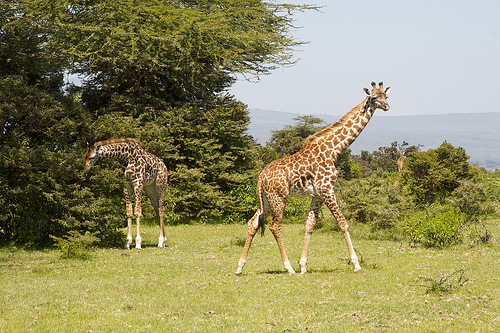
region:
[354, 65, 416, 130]
the head of a giraffe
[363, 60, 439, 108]
the eyes of a giraffe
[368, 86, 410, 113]
the mouth of a giraffe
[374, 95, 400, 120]
the nose of a giraffe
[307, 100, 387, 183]
the neck of a giraffe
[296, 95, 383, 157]
the main of a giraffe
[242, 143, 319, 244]
a tail of a giraffe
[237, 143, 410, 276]
the legs of a giraffe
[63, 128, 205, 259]
a book near a tree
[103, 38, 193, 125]
green leaves on a tree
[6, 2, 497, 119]
clear light blue sky with no clouds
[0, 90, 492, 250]
tall bushes planted behind giraffes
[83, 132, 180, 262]
baby giraffe eating bushes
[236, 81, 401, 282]
young giraffe standing in grassy field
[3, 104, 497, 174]
tall mountains sitting in background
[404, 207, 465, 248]
small bush sitting near giraffe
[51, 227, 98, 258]
smaller bush sitting near larger bush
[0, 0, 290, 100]
tall trees sitting behind bushes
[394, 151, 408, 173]
tall animal hiding in bushes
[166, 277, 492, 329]
many patches of brown grass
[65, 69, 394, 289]
Two giraffes in the wild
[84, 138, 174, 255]
Giraffe eating leaves off of the tree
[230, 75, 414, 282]
Giraffe looking to the right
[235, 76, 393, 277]
Giraffe walking away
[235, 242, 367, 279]
Four white legs on giraffe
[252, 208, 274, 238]
Black hair on giraffe tail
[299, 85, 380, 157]
Brown and white mane on giraffe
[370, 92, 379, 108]
Black eye on giraffe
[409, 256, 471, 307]
Small green bush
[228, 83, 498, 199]
Mountains in the distance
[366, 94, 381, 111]
the eye of a giraffe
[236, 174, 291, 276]
the tail of a giraffe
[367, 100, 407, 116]
the nose of a giraffe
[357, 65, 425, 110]
the ears of a giraffe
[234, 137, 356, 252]
the body of a giraffe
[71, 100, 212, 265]
a giraffe near a tree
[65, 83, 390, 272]
giraffes in the grass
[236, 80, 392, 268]
a giraffe standing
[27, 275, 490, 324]
grass they are standing on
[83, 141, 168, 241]
a giraffe bent over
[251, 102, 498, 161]
a hill in the background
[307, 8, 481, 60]
the clear blue sky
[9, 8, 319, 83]
the branch of the tree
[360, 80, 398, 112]
the face of the giraffe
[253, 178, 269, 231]
the tail of the giraffe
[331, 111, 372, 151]
the neck of the giraffe